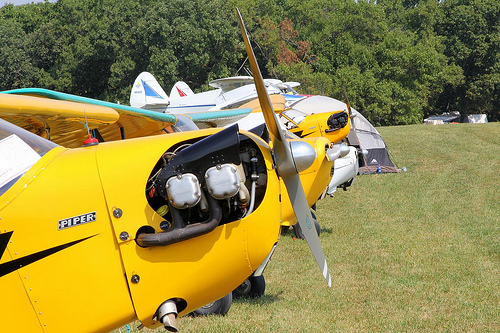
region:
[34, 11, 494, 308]
picture taken outdoors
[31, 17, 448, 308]
picture taken during the day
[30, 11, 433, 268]
planes on a field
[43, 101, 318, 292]
the plane is yellow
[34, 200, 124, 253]
the plane says piper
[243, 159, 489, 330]
the plane is on short cut grass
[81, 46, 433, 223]
the plane's propeller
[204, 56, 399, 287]
the propeller is on the front of the plane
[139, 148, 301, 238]
the engine is exposed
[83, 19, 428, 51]
the tall trees behind the airplanes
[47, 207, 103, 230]
company ID/logo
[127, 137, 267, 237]
exposed engine of the plane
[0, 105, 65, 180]
the cockpit window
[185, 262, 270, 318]
two wheels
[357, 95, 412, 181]
portion of a tent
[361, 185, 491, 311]
field of brown and green grass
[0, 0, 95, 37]
thick trees and a small piece of sky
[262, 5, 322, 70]
dry, brown tree surrounded by green ones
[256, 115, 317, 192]
propeller attached to the nose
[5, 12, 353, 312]
airplanes lined up on a field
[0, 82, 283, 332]
the plane is parked on a field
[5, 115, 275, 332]
the plane is painted yellow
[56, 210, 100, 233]
the plane logo is on the side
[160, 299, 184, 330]
an exhaust pipe protrudes from plane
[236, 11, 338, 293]
a propeller is in front of the plane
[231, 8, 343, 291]
the propeller is upright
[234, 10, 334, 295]
the propeller is grey in color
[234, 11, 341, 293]
the propeller is made of wood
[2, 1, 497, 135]
a batch of trees is in the background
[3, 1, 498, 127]
the trees are green in color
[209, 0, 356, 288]
A shiny metal propeller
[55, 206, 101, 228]
The label says "Piper"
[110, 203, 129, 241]
Two small metal screws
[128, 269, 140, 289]
A small screw on the plane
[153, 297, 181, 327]
A small exhaust pipe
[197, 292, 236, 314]
A small black tire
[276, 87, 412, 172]
A grey and black tent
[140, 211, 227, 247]
Thick black metal tubing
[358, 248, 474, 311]
The grass is very short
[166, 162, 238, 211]
Two metal boxes in the plane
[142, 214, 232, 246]
A thick metal tube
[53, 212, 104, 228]
The plane says "piper"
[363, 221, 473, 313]
The grass is short by the planes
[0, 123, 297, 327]
A small yellow plane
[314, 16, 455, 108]
Trees in the distance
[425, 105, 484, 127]
Small buildings by the trees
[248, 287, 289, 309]
Shadow of the plane's wheel